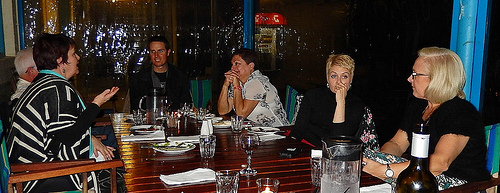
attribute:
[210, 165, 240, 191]
glass — brown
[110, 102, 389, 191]
table — brown